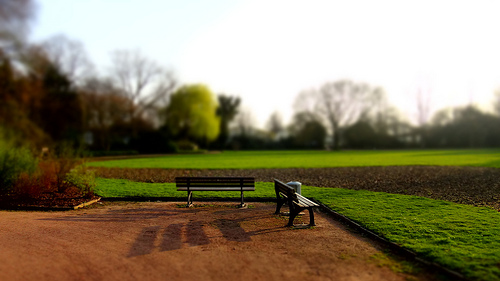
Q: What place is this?
A: It is a park.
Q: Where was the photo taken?
A: It was taken at the park.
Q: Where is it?
A: This is at the park.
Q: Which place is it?
A: It is a park.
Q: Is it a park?
A: Yes, it is a park.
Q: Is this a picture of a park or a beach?
A: It is showing a park.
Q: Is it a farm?
A: No, it is a park.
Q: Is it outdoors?
A: Yes, it is outdoors.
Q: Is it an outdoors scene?
A: Yes, it is outdoors.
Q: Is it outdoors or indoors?
A: It is outdoors.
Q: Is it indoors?
A: No, it is outdoors.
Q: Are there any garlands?
A: No, there are no garlands.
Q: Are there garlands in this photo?
A: No, there are no garlands.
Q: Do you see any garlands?
A: No, there are no garlands.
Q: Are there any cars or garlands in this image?
A: No, there are no garlands or cars.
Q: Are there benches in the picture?
A: Yes, there is a bench.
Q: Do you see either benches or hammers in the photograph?
A: Yes, there is a bench.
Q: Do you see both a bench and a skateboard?
A: No, there is a bench but no skateboards.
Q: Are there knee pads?
A: No, there are no knee pads.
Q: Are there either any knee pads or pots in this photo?
A: No, there are no knee pads or pots.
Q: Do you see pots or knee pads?
A: No, there are no knee pads or pots.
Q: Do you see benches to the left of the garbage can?
A: Yes, there is a bench to the left of the garbage can.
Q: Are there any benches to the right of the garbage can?
A: No, the bench is to the left of the garbage can.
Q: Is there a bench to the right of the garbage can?
A: No, the bench is to the left of the garbage can.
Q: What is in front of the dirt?
A: The bench is in front of the dirt.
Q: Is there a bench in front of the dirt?
A: Yes, there is a bench in front of the dirt.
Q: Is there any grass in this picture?
A: Yes, there is grass.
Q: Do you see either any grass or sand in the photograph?
A: Yes, there is grass.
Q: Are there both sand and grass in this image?
A: No, there is grass but no sand.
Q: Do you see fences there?
A: No, there are no fences.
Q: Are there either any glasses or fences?
A: No, there are no fences or glasses.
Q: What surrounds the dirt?
A: The grass surrounds the dirt.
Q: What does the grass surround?
A: The grass surrounds the dirt.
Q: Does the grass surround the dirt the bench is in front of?
A: Yes, the grass surrounds the dirt.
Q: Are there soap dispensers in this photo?
A: No, there are no soap dispensers.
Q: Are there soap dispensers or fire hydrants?
A: No, there are no soap dispensers or fire hydrants.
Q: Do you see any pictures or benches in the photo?
A: Yes, there is a bench.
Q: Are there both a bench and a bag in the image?
A: No, there is a bench but no bags.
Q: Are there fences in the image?
A: No, there are no fences.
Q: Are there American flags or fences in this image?
A: No, there are no fences or American flags.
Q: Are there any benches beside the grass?
A: Yes, there is a bench beside the grass.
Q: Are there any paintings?
A: No, there are no paintings.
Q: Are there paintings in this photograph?
A: No, there are no paintings.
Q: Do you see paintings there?
A: No, there are no paintings.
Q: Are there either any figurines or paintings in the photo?
A: No, there are no paintings or figurines.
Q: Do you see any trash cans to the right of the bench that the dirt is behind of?
A: Yes, there is a trash can to the right of the bench.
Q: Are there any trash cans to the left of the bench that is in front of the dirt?
A: No, the trash can is to the right of the bench.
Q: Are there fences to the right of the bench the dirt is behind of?
A: No, there is a trash can to the right of the bench.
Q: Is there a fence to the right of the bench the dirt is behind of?
A: No, there is a trash can to the right of the bench.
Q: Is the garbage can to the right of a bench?
A: Yes, the garbage can is to the right of a bench.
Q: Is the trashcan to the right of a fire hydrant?
A: No, the trashcan is to the right of a bench.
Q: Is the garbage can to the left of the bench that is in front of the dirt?
A: No, the garbage can is to the right of the bench.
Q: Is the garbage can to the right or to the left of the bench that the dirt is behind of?
A: The garbage can is to the right of the bench.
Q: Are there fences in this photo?
A: No, there are no fences.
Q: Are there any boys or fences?
A: No, there are no fences or boys.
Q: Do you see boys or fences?
A: No, there are no fences or boys.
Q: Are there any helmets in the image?
A: No, there are no helmets.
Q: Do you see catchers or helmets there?
A: No, there are no helmets or catchers.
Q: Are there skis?
A: No, there are no skis.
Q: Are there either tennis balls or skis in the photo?
A: No, there are no skis or tennis balls.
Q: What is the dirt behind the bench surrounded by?
A: The dirt is surrounded by the grass.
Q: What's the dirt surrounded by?
A: The dirt is surrounded by the grass.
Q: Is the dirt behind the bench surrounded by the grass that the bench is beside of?
A: Yes, the dirt is surrounded by the grass.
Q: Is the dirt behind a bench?
A: Yes, the dirt is behind a bench.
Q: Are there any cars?
A: No, there are no cars.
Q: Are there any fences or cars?
A: No, there are no cars or fences.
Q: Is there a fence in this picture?
A: No, there are no fences.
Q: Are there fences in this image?
A: No, there are no fences.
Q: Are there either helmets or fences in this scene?
A: No, there are no fences or helmets.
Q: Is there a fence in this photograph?
A: No, there are no fences.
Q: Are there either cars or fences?
A: No, there are no fences or cars.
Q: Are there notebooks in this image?
A: No, there are no notebooks.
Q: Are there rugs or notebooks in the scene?
A: No, there are no notebooks or rugs.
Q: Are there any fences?
A: No, there are no fences.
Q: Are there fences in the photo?
A: No, there are no fences.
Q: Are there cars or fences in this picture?
A: No, there are no fences or cars.